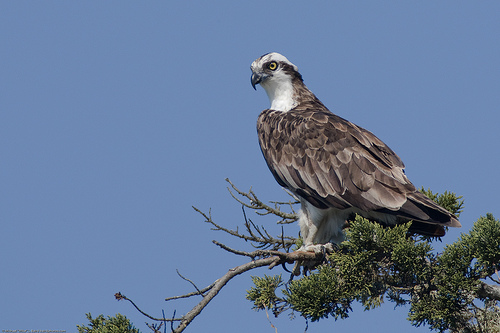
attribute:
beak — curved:
[245, 74, 260, 89]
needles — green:
[256, 216, 496, 332]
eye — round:
[264, 52, 279, 74]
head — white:
[248, 50, 305, 106]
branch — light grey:
[185, 198, 283, 305]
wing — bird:
[318, 116, 425, 214]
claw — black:
[321, 245, 326, 255]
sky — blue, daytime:
[318, 3, 495, 88]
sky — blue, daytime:
[2, 0, 243, 167]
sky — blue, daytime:
[0, 188, 183, 257]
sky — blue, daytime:
[425, 83, 495, 177]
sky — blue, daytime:
[0, 278, 60, 330]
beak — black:
[248, 70, 263, 90]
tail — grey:
[355, 165, 461, 237]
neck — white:
[251, 76, 327, 105]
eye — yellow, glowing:
[266, 61, 276, 70]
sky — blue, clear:
[3, 3, 498, 330]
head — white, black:
[252, 51, 311, 111]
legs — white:
[302, 204, 340, 248]